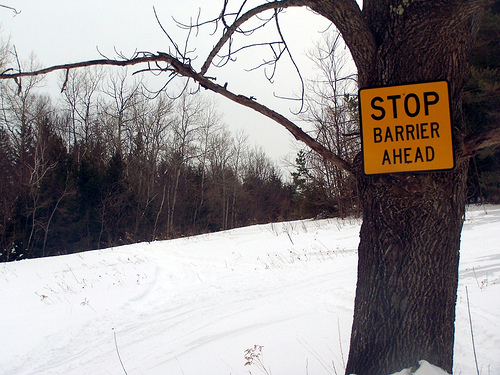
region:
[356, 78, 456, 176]
Yellow sign with black lettering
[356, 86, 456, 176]
Caution sign indicating a barrier ahead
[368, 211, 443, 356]
Grey bark on a tree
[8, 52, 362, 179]
A tree limb with no leaves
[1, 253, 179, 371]
Snow covered ground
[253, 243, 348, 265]
Weeds poking up through the snow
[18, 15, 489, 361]
A winter woodland scene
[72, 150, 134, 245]
Evergreens hiding amoung the leaveless trees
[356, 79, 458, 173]
A yellow sign commanding people to Stop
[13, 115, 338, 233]
A forest in the background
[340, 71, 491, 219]
the sign is yellow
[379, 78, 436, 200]
the sign is yellow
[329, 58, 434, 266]
the sign is yellow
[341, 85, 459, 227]
yellow sing put on tree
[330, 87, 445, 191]
words on yellow sign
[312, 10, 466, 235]
warning sign put on tree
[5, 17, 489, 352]
large tree with a sign on top of it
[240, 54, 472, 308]
sign nailed to a tree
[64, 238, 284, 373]
snow on the ground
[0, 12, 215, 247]
barren trees on top of snow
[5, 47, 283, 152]
tree branch without leaves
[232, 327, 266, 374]
small bush sticking up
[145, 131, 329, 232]
trees without any leaves on them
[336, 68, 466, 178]
a yellow singal board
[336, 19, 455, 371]
a big tree on island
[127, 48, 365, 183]
a small stem of tree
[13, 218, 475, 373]
a beautiful view of snow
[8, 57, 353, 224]
a large group of trees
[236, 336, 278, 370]
the top part of flower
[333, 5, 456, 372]
a tree with design board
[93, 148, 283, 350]
trees snow side by side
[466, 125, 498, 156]
a small part of stem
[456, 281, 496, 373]
a small thin stem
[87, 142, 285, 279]
the tress are dark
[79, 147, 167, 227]
the tress are dark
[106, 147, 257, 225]
the tress are dark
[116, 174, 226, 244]
the tress are dark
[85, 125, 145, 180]
the tress are dark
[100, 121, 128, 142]
the tress are dark